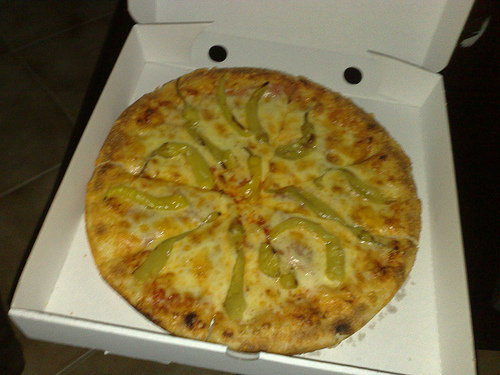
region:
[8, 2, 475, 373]
Baked pizza in white cardboard box.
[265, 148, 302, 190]
part of a pizza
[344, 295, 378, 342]
edge of a pizza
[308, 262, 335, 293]
part of a pizza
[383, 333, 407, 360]
part of a pizza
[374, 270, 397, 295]
dge of a pizza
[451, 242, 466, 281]
edge of a pizza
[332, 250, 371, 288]
part of a pizza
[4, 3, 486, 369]
Food in a box.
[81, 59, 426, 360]
A round pizza pie.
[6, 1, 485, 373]
A white cardboard box.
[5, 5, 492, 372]
An open pizza box.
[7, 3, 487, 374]
Pizza in a pizza box.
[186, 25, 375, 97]
Two holes in a pizza box.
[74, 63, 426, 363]
Peppers on top of a pizza.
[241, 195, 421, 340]
One triangular pizza slice.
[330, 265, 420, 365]
Grease on a pizza box.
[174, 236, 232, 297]
White cheese on a pizza.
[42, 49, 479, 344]
a pizza in a box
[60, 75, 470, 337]
a pizza sitting in a box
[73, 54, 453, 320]
a pizza with cheese on it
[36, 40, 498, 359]
a cheese pizza in a box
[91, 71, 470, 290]
peppers on a pizza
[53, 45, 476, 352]
a white box with a pizza in it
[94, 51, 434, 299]
the crust on a pizza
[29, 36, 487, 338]
a pizza in a box on the floor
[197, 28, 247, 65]
a hole in apizza box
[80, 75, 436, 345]
a cheese pizza in a big white pizza box